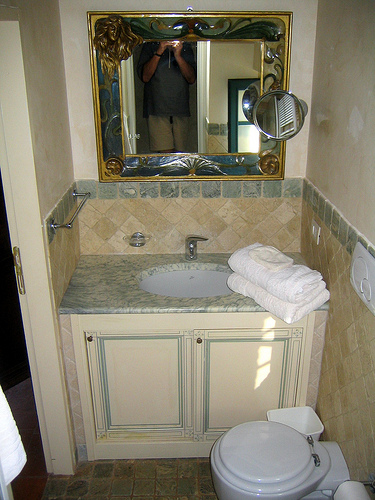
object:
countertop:
[56, 251, 331, 315]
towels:
[227, 242, 330, 323]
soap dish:
[120, 229, 152, 251]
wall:
[79, 178, 303, 256]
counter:
[56, 252, 329, 464]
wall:
[299, 0, 375, 482]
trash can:
[267, 404, 324, 442]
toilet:
[206, 420, 349, 498]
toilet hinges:
[309, 451, 321, 469]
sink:
[135, 260, 237, 302]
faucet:
[184, 235, 208, 263]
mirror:
[250, 86, 303, 142]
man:
[134, 40, 199, 154]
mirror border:
[85, 8, 293, 183]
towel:
[224, 241, 331, 325]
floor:
[0, 376, 218, 498]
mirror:
[94, 11, 289, 177]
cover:
[210, 418, 318, 497]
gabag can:
[264, 401, 325, 443]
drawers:
[70, 314, 316, 445]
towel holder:
[48, 189, 93, 232]